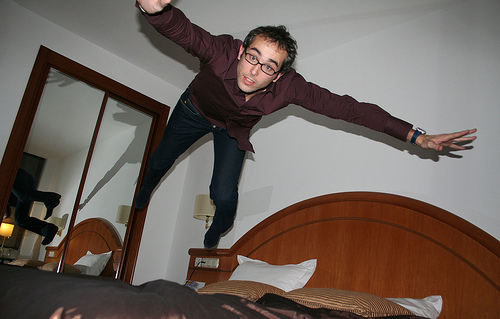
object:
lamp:
[193, 194, 216, 230]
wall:
[0, 0, 499, 285]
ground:
[303, 3, 500, 217]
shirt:
[138, 3, 413, 153]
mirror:
[0, 44, 170, 283]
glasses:
[244, 45, 281, 76]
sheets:
[0, 263, 431, 319]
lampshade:
[116, 205, 133, 224]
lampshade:
[193, 194, 216, 222]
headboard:
[218, 191, 500, 319]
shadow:
[44, 69, 154, 211]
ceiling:
[10, 0, 462, 91]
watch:
[411, 127, 426, 146]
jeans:
[142, 86, 246, 233]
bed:
[0, 191, 500, 319]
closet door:
[0, 44, 171, 284]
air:
[0, 0, 500, 80]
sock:
[204, 227, 222, 248]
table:
[0, 257, 20, 266]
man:
[135, 0, 477, 251]